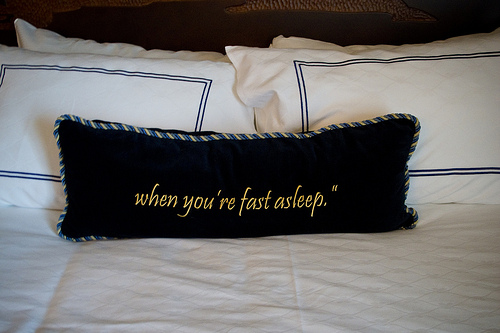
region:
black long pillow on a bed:
[48, 103, 428, 250]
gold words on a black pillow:
[123, 173, 345, 227]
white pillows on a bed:
[1, 11, 496, 207]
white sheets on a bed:
[3, 200, 498, 329]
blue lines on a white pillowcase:
[290, 54, 499, 182]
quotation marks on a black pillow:
[331, 179, 341, 194]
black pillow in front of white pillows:
[44, 105, 430, 247]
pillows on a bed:
[0, 14, 499, 245]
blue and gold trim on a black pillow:
[51, 110, 426, 145]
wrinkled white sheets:
[0, 212, 499, 326]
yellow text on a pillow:
[125, 182, 340, 214]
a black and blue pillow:
[40, 116, 412, 233]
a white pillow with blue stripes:
[227, 35, 497, 190]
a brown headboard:
[0, 0, 495, 52]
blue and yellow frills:
[60, 119, 425, 144]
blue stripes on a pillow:
[11, 62, 203, 87]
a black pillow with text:
[53, 115, 416, 235]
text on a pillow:
[136, 180, 343, 214]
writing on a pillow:
[132, 181, 347, 217]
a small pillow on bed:
[51, 112, 425, 243]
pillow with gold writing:
[48, 111, 424, 245]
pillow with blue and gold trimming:
[52, 110, 424, 243]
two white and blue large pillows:
[2, 29, 498, 209]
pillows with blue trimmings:
[0, 49, 499, 189]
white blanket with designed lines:
[1, 204, 498, 331]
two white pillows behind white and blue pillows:
[12, 15, 499, 65]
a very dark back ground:
[0, 1, 498, 58]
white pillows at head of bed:
[1, 17, 498, 217]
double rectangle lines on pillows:
[0, 49, 499, 183]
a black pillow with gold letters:
[37, 111, 432, 252]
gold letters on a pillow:
[118, 179, 360, 223]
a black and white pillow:
[0, 32, 257, 214]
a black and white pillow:
[224, 31, 498, 196]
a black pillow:
[45, 112, 430, 244]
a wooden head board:
[1, 2, 498, 64]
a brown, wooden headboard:
[5, 2, 496, 54]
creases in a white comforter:
[32, 251, 336, 332]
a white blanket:
[2, 209, 497, 331]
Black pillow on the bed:
[58, 114, 439, 252]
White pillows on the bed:
[47, 33, 489, 120]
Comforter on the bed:
[56, 238, 458, 332]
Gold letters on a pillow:
[128, 172, 344, 216]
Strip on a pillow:
[41, 59, 251, 150]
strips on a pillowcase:
[281, 54, 351, 125]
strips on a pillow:
[31, 99, 448, 241]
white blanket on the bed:
[131, 238, 412, 330]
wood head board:
[138, 6, 333, 34]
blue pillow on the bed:
[49, 92, 489, 278]